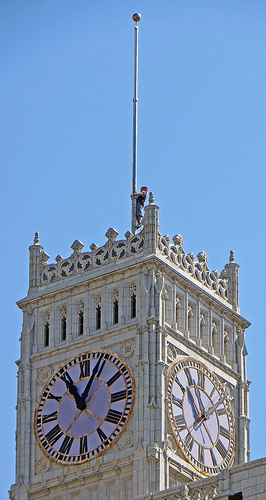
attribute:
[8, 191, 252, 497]
tower —  white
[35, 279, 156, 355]
windows — narrow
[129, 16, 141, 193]
pole — metal, flag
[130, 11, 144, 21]
ball — silver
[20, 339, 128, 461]
clock — white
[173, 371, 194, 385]
numerals — roman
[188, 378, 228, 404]
numerals — roman, black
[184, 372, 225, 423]
hands — black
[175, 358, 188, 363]
boarder — gold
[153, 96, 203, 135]
sky — blue, clear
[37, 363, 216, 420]
clocks — large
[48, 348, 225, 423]
clocks — large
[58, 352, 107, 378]
numeral — roman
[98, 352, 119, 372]
numeral — roman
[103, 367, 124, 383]
numeral — roman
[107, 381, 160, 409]
numeral — roman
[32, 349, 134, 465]
clock — white, black, gold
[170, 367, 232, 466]
numbers — roman numeral